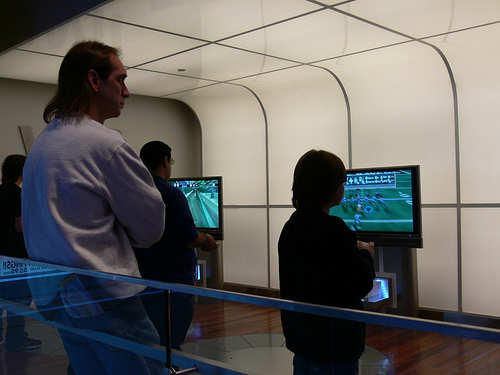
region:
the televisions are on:
[325, 160, 428, 259]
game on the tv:
[340, 170, 415, 228]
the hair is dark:
[294, 152, 337, 218]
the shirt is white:
[30, 119, 147, 271]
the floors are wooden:
[190, 285, 293, 372]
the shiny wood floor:
[0, 290, 499, 373]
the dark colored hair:
[292, 150, 349, 211]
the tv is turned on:
[331, 165, 426, 249]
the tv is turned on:
[171, 176, 224, 241]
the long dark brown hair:
[42, 41, 121, 126]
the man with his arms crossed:
[20, 37, 171, 372]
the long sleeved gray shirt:
[22, 115, 167, 312]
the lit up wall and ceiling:
[0, 0, 498, 315]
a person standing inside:
[244, 148, 412, 368]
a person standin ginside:
[97, 73, 247, 373]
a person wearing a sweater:
[19, 34, 179, 374]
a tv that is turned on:
[289, 137, 415, 283]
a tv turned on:
[150, 163, 244, 300]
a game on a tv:
[287, 120, 443, 334]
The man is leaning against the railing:
[43, 37, 198, 372]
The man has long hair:
[41, 41, 113, 121]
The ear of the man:
[81, 70, 108, 97]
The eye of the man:
[113, 72, 134, 86]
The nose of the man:
[119, 83, 136, 97]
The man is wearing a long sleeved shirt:
[16, 114, 169, 305]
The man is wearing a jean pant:
[41, 307, 166, 373]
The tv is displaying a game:
[338, 158, 452, 251]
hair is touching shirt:
[54, 47, 93, 142]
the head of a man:
[35, 29, 136, 134]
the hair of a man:
[44, 81, 86, 129]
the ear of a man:
[77, 63, 108, 98]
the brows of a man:
[110, 66, 138, 81]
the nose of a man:
[115, 81, 135, 102]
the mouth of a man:
[110, 96, 131, 111]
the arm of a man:
[61, 133, 185, 244]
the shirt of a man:
[28, 125, 170, 302]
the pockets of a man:
[48, 306, 120, 343]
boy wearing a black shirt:
[276, 212, 371, 337]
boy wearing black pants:
[291, 338, 353, 372]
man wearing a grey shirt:
[20, 110, 166, 285]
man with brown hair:
[43, 40, 121, 123]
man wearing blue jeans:
[41, 293, 169, 369]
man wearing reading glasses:
[166, 156, 174, 162]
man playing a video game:
[135, 138, 225, 278]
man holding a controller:
[353, 230, 375, 256]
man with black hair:
[3, 146, 26, 185]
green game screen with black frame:
[328, 166, 423, 248]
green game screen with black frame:
[167, 176, 224, 241]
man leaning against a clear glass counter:
[18, 41, 167, 373]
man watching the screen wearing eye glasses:
[138, 141, 220, 355]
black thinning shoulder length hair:
[41, 39, 122, 129]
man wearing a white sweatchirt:
[17, 39, 167, 373]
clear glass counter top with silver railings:
[1, 254, 498, 372]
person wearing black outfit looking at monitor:
[276, 148, 374, 374]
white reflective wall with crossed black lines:
[3, 4, 498, 322]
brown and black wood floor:
[2, 292, 498, 372]